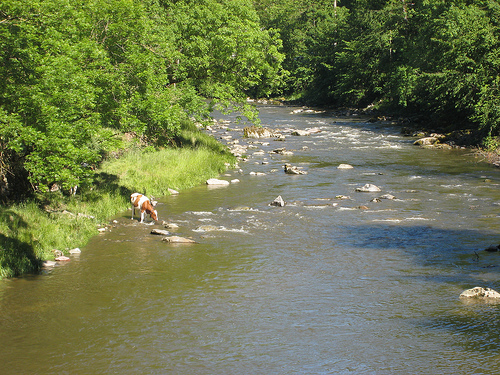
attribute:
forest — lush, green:
[264, 1, 499, 137]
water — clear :
[41, 282, 328, 357]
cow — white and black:
[124, 178, 171, 233]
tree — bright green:
[20, 14, 246, 204]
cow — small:
[132, 181, 171, 234]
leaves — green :
[131, 92, 157, 115]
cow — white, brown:
[122, 192, 175, 222]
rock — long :
[282, 126, 324, 138]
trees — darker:
[281, 8, 484, 145]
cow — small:
[129, 185, 162, 223]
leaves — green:
[13, 5, 258, 176]